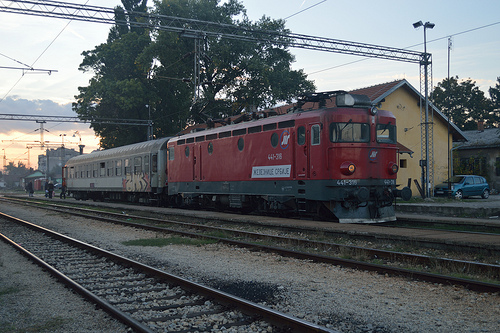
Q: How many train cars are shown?
A: Two.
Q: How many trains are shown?
A: One.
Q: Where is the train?
A: On tracks.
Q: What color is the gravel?
A: Gray.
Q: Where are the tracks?
A: On gravel.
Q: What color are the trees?
A: Green.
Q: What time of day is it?
A: Sunset.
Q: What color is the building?
A: Yellow.